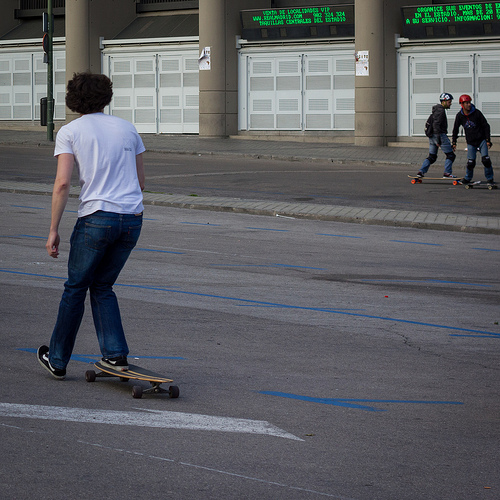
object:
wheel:
[451, 180, 460, 185]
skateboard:
[405, 174, 465, 186]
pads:
[426, 151, 437, 163]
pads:
[464, 156, 474, 171]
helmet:
[438, 92, 454, 102]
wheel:
[118, 376, 129, 382]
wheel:
[130, 385, 142, 399]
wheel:
[464, 184, 469, 189]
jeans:
[47, 209, 144, 375]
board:
[92, 356, 172, 383]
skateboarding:
[36, 70, 185, 399]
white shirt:
[53, 113, 146, 218]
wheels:
[166, 383, 180, 398]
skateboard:
[83, 360, 179, 398]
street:
[0, 131, 500, 499]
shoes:
[34, 344, 67, 377]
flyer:
[354, 49, 369, 76]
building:
[0, 0, 500, 152]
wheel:
[85, 367, 98, 384]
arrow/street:
[1, 401, 304, 444]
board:
[242, 7, 354, 36]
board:
[399, 1, 498, 23]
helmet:
[456, 95, 473, 106]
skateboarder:
[451, 94, 492, 183]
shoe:
[96, 356, 129, 371]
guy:
[36, 70, 146, 378]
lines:
[255, 386, 376, 414]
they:
[414, 90, 495, 186]